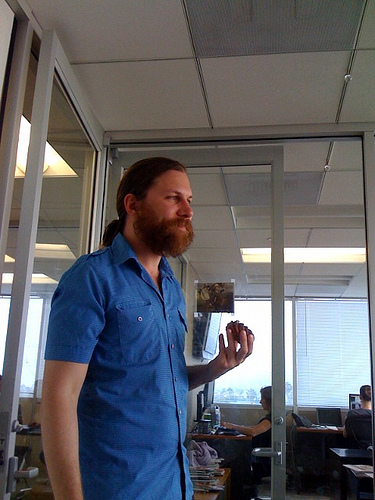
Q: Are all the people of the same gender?
A: No, they are both male and female.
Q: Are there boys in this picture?
A: No, there are no boys.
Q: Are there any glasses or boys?
A: No, there are no boys or glasses.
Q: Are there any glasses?
A: No, there are no glasses.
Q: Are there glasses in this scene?
A: No, there are no glasses.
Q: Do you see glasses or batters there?
A: No, there are no glasses or batters.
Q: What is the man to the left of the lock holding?
A: The man is holding the doughnut.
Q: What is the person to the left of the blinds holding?
A: The man is holding the doughnut.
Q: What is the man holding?
A: The man is holding the doughnut.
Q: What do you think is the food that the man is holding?
A: The food is a donut.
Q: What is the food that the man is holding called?
A: The food is a donut.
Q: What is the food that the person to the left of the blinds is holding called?
A: The food is a donut.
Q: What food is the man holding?
A: The man is holding the donut.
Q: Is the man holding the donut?
A: Yes, the man is holding the donut.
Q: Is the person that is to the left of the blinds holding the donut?
A: Yes, the man is holding the donut.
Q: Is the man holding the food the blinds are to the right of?
A: Yes, the man is holding the donut.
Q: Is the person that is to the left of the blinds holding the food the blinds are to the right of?
A: Yes, the man is holding the donut.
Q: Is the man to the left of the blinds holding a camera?
A: No, the man is holding the donut.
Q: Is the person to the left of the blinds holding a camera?
A: No, the man is holding the donut.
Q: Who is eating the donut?
A: The man is eating the donut.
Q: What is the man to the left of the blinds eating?
A: The man is eating a donut.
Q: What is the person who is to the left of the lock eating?
A: The man is eating a donut.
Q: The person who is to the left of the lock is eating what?
A: The man is eating a donut.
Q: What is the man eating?
A: The man is eating a donut.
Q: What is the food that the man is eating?
A: The food is a donut.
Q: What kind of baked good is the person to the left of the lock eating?
A: The man is eating a doughnut.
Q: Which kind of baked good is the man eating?
A: The man is eating a doughnut.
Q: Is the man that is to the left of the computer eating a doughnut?
A: Yes, the man is eating a doughnut.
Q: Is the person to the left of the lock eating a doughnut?
A: Yes, the man is eating a doughnut.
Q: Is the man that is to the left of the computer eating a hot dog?
A: No, the man is eating a doughnut.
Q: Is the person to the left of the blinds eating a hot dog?
A: No, the man is eating a doughnut.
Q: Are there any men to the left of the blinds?
A: Yes, there is a man to the left of the blinds.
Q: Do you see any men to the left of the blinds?
A: Yes, there is a man to the left of the blinds.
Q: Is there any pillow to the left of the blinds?
A: No, there is a man to the left of the blinds.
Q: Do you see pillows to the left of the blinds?
A: No, there is a man to the left of the blinds.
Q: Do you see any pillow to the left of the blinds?
A: No, there is a man to the left of the blinds.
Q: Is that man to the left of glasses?
A: No, the man is to the left of the blinds.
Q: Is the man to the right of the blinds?
A: No, the man is to the left of the blinds.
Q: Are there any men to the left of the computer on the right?
A: Yes, there is a man to the left of the computer.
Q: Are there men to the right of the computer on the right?
A: No, the man is to the left of the computer.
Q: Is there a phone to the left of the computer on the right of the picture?
A: No, there is a man to the left of the computer.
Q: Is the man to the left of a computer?
A: Yes, the man is to the left of a computer.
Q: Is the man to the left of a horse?
A: No, the man is to the left of a computer.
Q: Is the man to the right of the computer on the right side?
A: No, the man is to the left of the computer.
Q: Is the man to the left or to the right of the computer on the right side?
A: The man is to the left of the computer.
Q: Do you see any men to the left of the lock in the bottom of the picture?
A: Yes, there is a man to the left of the lock.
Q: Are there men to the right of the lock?
A: No, the man is to the left of the lock.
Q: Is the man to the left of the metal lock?
A: Yes, the man is to the left of the lock.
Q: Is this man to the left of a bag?
A: No, the man is to the left of the lock.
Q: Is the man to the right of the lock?
A: No, the man is to the left of the lock.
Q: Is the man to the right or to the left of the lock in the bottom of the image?
A: The man is to the left of the lock.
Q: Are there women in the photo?
A: Yes, there are women.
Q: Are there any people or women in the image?
A: Yes, there are women.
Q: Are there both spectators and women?
A: No, there are women but no spectators.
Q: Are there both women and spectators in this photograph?
A: No, there are women but no spectators.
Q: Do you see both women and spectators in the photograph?
A: No, there are women but no spectators.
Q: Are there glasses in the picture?
A: No, there are no glasses.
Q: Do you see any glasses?
A: No, there are no glasses.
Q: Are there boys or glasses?
A: No, there are no glasses or boys.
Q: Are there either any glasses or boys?
A: No, there are no glasses or boys.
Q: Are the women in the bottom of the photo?
A: Yes, the women are in the bottom of the image.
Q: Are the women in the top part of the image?
A: No, the women are in the bottom of the image.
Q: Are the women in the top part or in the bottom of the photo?
A: The women are in the bottom of the image.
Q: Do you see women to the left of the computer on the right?
A: Yes, there are women to the left of the computer.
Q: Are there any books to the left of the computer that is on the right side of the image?
A: No, there are women to the left of the computer.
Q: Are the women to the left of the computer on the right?
A: Yes, the women are to the left of the computer.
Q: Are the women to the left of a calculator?
A: No, the women are to the left of the computer.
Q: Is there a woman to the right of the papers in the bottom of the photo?
A: Yes, there are women to the right of the papers.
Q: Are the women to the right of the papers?
A: Yes, the women are to the right of the papers.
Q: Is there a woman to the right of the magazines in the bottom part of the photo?
A: Yes, there are women to the right of the magazines.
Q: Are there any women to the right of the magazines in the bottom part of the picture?
A: Yes, there are women to the right of the magazines.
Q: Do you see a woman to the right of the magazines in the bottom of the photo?
A: Yes, there are women to the right of the magazines.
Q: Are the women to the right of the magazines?
A: Yes, the women are to the right of the magazines.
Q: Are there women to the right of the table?
A: Yes, there are women to the right of the table.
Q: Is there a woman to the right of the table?
A: Yes, there are women to the right of the table.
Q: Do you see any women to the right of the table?
A: Yes, there are women to the right of the table.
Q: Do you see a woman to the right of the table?
A: Yes, there are women to the right of the table.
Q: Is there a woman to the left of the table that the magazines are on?
A: No, the women are to the right of the table.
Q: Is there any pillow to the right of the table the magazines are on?
A: No, there are women to the right of the table.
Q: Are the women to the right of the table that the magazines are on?
A: Yes, the women are to the right of the table.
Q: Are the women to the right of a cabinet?
A: No, the women are to the right of the table.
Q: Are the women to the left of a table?
A: No, the women are to the right of a table.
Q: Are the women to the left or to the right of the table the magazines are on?
A: The women are to the right of the table.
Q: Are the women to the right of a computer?
A: Yes, the women are to the right of a computer.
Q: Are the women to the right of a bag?
A: No, the women are to the right of a computer.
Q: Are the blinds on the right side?
A: Yes, the blinds are on the right of the image.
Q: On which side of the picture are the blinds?
A: The blinds are on the right of the image.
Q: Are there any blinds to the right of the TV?
A: Yes, there are blinds to the right of the TV.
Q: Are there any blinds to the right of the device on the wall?
A: Yes, there are blinds to the right of the TV.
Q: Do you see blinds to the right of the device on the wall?
A: Yes, there are blinds to the right of the TV.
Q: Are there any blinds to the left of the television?
A: No, the blinds are to the right of the television.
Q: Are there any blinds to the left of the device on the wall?
A: No, the blinds are to the right of the television.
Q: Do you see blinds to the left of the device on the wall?
A: No, the blinds are to the right of the television.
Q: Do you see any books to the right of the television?
A: No, there are blinds to the right of the television.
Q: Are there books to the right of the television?
A: No, there are blinds to the right of the television.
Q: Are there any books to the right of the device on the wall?
A: No, there are blinds to the right of the television.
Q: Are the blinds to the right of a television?
A: Yes, the blinds are to the right of a television.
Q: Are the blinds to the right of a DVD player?
A: No, the blinds are to the right of a television.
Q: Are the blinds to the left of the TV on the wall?
A: No, the blinds are to the right of the television.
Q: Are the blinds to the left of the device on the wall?
A: No, the blinds are to the right of the television.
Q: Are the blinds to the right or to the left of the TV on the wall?
A: The blinds are to the right of the TV.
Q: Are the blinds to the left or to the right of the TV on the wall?
A: The blinds are to the right of the TV.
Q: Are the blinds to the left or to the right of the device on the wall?
A: The blinds are to the right of the TV.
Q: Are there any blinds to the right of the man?
A: Yes, there are blinds to the right of the man.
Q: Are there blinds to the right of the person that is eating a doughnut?
A: Yes, there are blinds to the right of the man.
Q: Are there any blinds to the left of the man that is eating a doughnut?
A: No, the blinds are to the right of the man.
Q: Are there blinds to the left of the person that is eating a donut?
A: No, the blinds are to the right of the man.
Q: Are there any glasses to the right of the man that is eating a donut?
A: No, there are blinds to the right of the man.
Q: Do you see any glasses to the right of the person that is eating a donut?
A: No, there are blinds to the right of the man.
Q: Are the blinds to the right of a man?
A: Yes, the blinds are to the right of a man.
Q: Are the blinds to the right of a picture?
A: No, the blinds are to the right of a man.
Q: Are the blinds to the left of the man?
A: No, the blinds are to the right of the man.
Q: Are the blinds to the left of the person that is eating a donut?
A: No, the blinds are to the right of the man.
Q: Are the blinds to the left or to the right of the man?
A: The blinds are to the right of the man.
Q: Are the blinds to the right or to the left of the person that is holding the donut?
A: The blinds are to the right of the man.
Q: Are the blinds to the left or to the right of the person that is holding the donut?
A: The blinds are to the right of the man.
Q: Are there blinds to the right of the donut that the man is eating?
A: Yes, there are blinds to the right of the donut.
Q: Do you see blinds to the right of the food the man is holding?
A: Yes, there are blinds to the right of the donut.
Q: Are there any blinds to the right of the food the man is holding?
A: Yes, there are blinds to the right of the donut.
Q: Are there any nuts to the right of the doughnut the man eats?
A: No, there are blinds to the right of the donut.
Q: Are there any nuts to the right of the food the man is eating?
A: No, there are blinds to the right of the donut.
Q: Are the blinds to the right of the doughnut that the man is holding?
A: Yes, the blinds are to the right of the donut.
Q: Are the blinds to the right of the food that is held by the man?
A: Yes, the blinds are to the right of the donut.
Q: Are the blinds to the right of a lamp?
A: No, the blinds are to the right of the donut.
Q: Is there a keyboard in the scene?
A: Yes, there is a keyboard.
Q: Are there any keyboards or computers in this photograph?
A: Yes, there is a keyboard.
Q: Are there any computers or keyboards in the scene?
A: Yes, there is a keyboard.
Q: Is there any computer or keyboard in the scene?
A: Yes, there is a keyboard.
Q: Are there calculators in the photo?
A: No, there are no calculators.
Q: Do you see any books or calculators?
A: No, there are no calculators or books.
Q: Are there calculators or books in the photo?
A: No, there are no calculators or books.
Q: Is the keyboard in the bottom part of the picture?
A: Yes, the keyboard is in the bottom of the image.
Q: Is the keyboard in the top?
A: No, the keyboard is in the bottom of the image.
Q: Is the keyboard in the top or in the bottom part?
A: The keyboard is in the bottom of the image.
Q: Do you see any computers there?
A: Yes, there is a computer.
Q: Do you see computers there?
A: Yes, there is a computer.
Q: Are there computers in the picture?
A: Yes, there is a computer.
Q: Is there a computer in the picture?
A: Yes, there is a computer.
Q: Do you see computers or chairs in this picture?
A: Yes, there is a computer.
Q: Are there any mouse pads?
A: No, there are no mouse pads.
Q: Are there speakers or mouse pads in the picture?
A: No, there are no mouse pads or speakers.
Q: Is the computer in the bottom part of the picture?
A: Yes, the computer is in the bottom of the image.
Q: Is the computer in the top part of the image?
A: No, the computer is in the bottom of the image.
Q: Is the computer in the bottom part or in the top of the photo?
A: The computer is in the bottom of the image.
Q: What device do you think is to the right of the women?
A: The device is a computer.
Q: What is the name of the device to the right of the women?
A: The device is a computer.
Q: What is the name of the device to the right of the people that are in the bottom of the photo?
A: The device is a computer.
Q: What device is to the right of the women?
A: The device is a computer.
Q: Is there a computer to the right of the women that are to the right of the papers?
A: Yes, there is a computer to the right of the women.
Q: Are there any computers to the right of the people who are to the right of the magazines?
A: Yes, there is a computer to the right of the women.